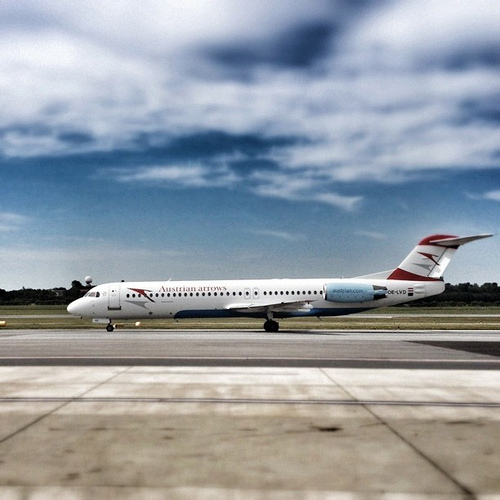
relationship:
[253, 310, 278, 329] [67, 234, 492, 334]
wheel of airline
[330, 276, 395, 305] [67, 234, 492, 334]
engine of airline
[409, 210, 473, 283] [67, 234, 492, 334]
tail of airline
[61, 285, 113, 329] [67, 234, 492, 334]
nose of airline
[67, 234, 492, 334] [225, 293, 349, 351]
airline has wing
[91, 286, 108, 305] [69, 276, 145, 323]
windows on cockpit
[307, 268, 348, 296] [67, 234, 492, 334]
propeller on airline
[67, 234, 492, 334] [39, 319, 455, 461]
airline on tarmac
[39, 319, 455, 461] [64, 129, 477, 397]
tarmac at airport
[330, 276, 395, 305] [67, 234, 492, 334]
engine on airline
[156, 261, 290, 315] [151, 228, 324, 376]
windows on side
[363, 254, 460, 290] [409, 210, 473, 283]
logo on tail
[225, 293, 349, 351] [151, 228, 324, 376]
wing on side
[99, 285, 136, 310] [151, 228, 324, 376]
door on side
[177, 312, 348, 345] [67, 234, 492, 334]
shadow of airline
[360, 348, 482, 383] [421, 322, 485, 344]
road has edge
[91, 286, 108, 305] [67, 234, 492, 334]
windows on airline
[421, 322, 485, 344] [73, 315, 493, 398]
edge of runway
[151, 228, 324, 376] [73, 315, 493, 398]
side of runway